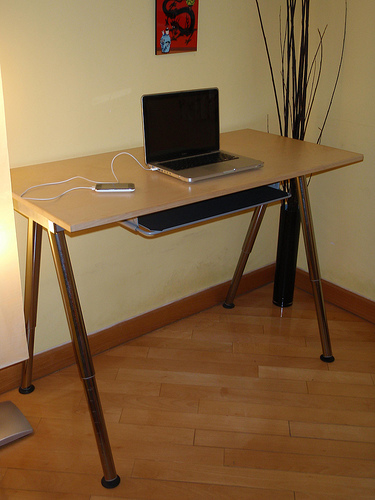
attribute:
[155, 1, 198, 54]
artwork — RED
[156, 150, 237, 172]
keyboard — Black 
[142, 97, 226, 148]
screen — laptop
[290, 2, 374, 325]
wall — WHITE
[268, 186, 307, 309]
pot — BLACK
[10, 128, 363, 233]
table — WOODEN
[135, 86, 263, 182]
laptop — keyboard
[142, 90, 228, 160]
screen — laptop, off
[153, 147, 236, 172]
keys — black